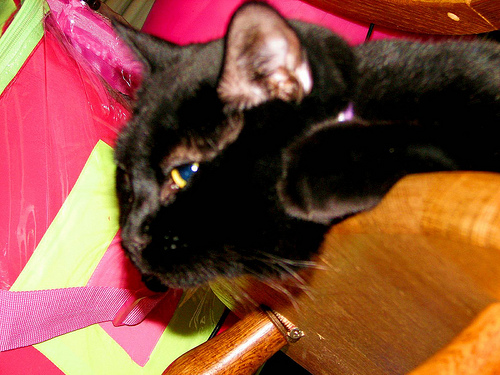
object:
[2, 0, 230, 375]
pattern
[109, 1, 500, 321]
cat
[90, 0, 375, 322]
head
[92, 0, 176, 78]
ear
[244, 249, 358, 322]
whisker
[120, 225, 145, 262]
nose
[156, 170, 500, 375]
chair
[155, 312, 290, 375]
leg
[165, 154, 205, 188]
reflection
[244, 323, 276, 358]
reflection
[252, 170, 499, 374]
table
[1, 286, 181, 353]
leash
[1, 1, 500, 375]
package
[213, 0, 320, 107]
ear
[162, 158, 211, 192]
eye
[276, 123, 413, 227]
paw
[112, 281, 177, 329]
buckle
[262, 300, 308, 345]
screw